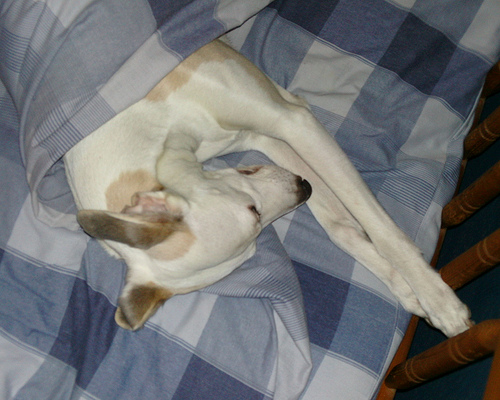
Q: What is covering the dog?
A: A comforter.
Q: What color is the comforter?
A: Blue.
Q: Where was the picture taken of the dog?
A: Bedroom.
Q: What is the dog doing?
A: Resting.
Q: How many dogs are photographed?
A: One.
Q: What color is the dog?
A: White and tan.